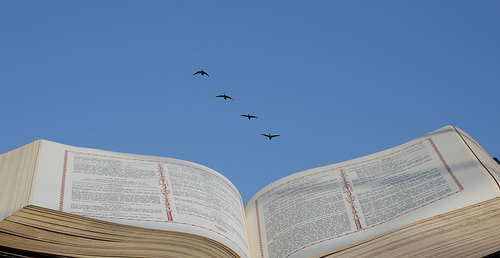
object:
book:
[0, 124, 500, 256]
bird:
[189, 67, 211, 78]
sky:
[0, 1, 499, 205]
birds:
[214, 93, 235, 101]